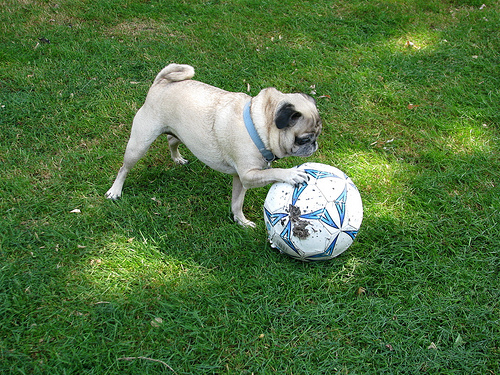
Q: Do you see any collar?
A: Yes, there is a collar.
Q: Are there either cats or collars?
A: Yes, there is a collar.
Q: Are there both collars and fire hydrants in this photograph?
A: No, there is a collar but no fire hydrants.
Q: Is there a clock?
A: No, there are no clocks.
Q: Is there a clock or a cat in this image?
A: No, there are no clocks or cats.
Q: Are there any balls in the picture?
A: Yes, there is a ball.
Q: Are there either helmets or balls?
A: Yes, there is a ball.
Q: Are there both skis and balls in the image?
A: No, there is a ball but no skis.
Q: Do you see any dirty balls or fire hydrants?
A: Yes, there is a dirty ball.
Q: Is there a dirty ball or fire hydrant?
A: Yes, there is a dirty ball.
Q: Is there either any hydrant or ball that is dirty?
A: Yes, the ball is dirty.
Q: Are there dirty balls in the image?
A: Yes, there is a dirty ball.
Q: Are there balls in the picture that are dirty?
A: Yes, there is a ball that is dirty.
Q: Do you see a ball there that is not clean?
A: Yes, there is a dirty ball.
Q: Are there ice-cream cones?
A: No, there are no ice-cream cones.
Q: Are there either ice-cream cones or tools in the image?
A: No, there are no ice-cream cones or tools.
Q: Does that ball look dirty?
A: Yes, the ball is dirty.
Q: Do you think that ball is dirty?
A: Yes, the ball is dirty.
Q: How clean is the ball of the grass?
A: The ball is dirty.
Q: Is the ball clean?
A: No, the ball is dirty.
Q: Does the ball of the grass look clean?
A: No, the ball is dirty.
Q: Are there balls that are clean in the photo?
A: No, there is a ball but it is dirty.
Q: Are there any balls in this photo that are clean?
A: No, there is a ball but it is dirty.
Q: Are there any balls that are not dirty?
A: No, there is a ball but it is dirty.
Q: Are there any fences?
A: No, there are no fences.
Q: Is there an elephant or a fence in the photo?
A: No, there are no fences or elephants.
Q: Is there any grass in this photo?
A: Yes, there is grass.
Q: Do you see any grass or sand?
A: Yes, there is grass.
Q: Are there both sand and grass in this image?
A: No, there is grass but no sand.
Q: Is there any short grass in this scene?
A: Yes, there is short grass.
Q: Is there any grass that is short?
A: Yes, there is grass that is short.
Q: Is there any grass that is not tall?
A: Yes, there is short grass.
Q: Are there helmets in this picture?
A: No, there are no helmets.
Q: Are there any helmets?
A: No, there are no helmets.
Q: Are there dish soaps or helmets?
A: No, there are no helmets or dish soaps.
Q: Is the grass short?
A: Yes, the grass is short.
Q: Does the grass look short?
A: Yes, the grass is short.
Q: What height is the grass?
A: The grass is short.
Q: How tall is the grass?
A: The grass is short.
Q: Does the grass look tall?
A: No, the grass is short.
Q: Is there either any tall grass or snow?
A: No, there is grass but it is short.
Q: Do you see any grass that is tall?
A: No, there is grass but it is short.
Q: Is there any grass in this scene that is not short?
A: No, there is grass but it is short.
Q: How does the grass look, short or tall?
A: The grass is short.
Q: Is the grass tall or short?
A: The grass is short.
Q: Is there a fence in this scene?
A: No, there are no fences.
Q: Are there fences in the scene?
A: No, there are no fences.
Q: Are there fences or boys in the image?
A: No, there are no fences or boys.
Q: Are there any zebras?
A: No, there are no zebras.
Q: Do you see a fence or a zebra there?
A: No, there are no zebras or fences.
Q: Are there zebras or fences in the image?
A: No, there are no zebras or fences.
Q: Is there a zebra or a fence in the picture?
A: No, there are no zebras or fences.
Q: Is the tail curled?
A: Yes, the tail is curled.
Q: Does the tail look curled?
A: Yes, the tail is curled.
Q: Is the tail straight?
A: No, the tail is curled.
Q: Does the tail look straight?
A: No, the tail is curled.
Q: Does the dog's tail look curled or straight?
A: The tail is curled.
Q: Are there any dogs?
A: Yes, there is a dog.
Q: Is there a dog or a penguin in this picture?
A: Yes, there is a dog.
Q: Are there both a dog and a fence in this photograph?
A: No, there is a dog but no fences.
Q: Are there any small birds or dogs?
A: Yes, there is a small dog.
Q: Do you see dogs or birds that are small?
A: Yes, the dog is small.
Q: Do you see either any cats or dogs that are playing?
A: Yes, the dog is playing.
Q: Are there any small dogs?
A: Yes, there is a small dog.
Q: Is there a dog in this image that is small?
A: Yes, there is a small dog.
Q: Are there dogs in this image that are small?
A: Yes, there is a dog that is small.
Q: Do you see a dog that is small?
A: Yes, there is a dog that is small.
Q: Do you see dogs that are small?
A: Yes, there is a dog that is small.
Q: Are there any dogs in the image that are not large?
A: Yes, there is a small dog.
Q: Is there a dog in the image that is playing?
A: Yes, there is a dog that is playing.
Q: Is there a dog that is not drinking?
A: Yes, there is a dog that is playing.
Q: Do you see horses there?
A: No, there are no horses.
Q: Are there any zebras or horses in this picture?
A: No, there are no horses or zebras.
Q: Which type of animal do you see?
A: The animal is a dog.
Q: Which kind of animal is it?
A: The animal is a dog.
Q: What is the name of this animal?
A: This is a dog.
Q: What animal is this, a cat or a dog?
A: This is a dog.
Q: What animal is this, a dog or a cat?
A: This is a dog.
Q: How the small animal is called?
A: The animal is a dog.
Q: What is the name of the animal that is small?
A: The animal is a dog.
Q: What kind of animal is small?
A: The animal is a dog.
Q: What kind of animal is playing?
A: The animal is a dog.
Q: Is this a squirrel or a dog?
A: This is a dog.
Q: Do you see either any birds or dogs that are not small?
A: No, there is a dog but it is small.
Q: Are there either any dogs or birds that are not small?
A: No, there is a dog but it is small.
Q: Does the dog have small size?
A: Yes, the dog is small.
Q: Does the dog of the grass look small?
A: Yes, the dog is small.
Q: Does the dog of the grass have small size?
A: Yes, the dog is small.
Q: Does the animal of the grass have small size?
A: Yes, the dog is small.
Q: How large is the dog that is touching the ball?
A: The dog is small.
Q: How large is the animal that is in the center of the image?
A: The dog is small.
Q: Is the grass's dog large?
A: No, the dog is small.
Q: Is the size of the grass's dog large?
A: No, the dog is small.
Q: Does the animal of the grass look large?
A: No, the dog is small.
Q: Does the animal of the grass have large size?
A: No, the dog is small.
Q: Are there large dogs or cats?
A: No, there is a dog but it is small.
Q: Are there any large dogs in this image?
A: No, there is a dog but it is small.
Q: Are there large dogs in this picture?
A: No, there is a dog but it is small.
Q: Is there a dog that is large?
A: No, there is a dog but it is small.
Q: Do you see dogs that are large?
A: No, there is a dog but it is small.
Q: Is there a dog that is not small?
A: No, there is a dog but it is small.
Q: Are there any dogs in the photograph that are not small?
A: No, there is a dog but it is small.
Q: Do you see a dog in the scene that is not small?
A: No, there is a dog but it is small.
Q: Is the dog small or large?
A: The dog is small.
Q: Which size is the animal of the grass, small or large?
A: The dog is small.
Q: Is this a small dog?
A: Yes, this is a small dog.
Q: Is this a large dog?
A: No, this is a small dog.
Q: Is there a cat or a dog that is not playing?
A: No, there is a dog but it is playing.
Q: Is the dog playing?
A: Yes, the dog is playing.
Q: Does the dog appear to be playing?
A: Yes, the dog is playing.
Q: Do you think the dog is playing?
A: Yes, the dog is playing.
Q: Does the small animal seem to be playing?
A: Yes, the dog is playing.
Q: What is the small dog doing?
A: The dog is playing.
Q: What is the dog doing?
A: The dog is playing.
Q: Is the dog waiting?
A: No, the dog is playing.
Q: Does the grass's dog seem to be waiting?
A: No, the dog is playing.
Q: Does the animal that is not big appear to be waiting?
A: No, the dog is playing.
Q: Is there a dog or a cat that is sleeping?
A: No, there is a dog but it is playing.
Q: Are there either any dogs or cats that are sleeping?
A: No, there is a dog but it is playing.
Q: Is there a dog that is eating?
A: No, there is a dog but it is playing.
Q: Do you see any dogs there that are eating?
A: No, there is a dog but it is playing.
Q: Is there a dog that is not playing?
A: No, there is a dog but it is playing.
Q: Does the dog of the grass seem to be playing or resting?
A: The dog is playing.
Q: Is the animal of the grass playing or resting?
A: The dog is playing.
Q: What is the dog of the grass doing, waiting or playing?
A: The dog is playing.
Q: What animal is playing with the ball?
A: The dog is playing with the ball.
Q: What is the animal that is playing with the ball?
A: The animal is a dog.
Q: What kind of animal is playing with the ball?
A: The animal is a dog.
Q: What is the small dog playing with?
A: The dog is playing with a ball.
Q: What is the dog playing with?
A: The dog is playing with a ball.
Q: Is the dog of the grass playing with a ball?
A: Yes, the dog is playing with a ball.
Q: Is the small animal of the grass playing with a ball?
A: Yes, the dog is playing with a ball.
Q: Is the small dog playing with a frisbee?
A: No, the dog is playing with a ball.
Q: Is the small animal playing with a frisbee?
A: No, the dog is playing with a ball.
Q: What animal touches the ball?
A: The dog touches the ball.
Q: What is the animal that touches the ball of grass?
A: The animal is a dog.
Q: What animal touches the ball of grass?
A: The animal is a dog.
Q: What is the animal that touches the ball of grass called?
A: The animal is a dog.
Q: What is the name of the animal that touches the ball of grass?
A: The animal is a dog.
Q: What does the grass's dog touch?
A: The dog touches the ball.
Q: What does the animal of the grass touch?
A: The dog touches the ball.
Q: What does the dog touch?
A: The dog touches the ball.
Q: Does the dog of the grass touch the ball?
A: Yes, the dog touches the ball.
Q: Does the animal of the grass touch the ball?
A: Yes, the dog touches the ball.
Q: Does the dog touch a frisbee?
A: No, the dog touches the ball.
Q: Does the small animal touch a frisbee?
A: No, the dog touches the ball.